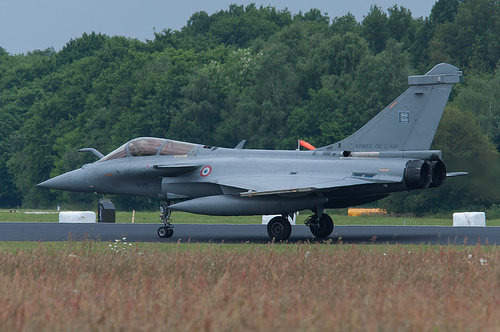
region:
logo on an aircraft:
[196, 161, 212, 181]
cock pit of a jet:
[96, 133, 197, 185]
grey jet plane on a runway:
[25, 72, 480, 249]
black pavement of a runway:
[10, 218, 104, 242]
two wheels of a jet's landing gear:
[257, 205, 349, 249]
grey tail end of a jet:
[327, 36, 468, 168]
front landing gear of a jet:
[155, 210, 176, 247]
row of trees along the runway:
[32, 30, 318, 132]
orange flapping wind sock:
[289, 128, 321, 165]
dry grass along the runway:
[39, 235, 479, 330]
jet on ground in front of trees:
[22, 51, 467, 258]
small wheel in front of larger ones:
[142, 211, 342, 241]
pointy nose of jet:
[25, 122, 160, 197]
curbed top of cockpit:
[96, 125, 201, 160]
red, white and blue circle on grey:
[191, 152, 216, 182]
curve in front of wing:
[320, 50, 455, 147]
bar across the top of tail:
[385, 56, 465, 116]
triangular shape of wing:
[205, 166, 350, 216]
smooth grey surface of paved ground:
[25, 212, 482, 247]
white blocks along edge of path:
[51, 208, 489, 229]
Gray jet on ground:
[69, 82, 426, 280]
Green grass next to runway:
[146, 235, 246, 260]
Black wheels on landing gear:
[136, 215, 383, 235]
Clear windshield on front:
[71, 133, 209, 218]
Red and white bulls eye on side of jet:
[195, 153, 232, 201]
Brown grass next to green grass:
[68, 242, 234, 326]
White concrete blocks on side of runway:
[40, 189, 165, 237]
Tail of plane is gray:
[330, 60, 467, 226]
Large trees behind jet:
[12, 37, 339, 159]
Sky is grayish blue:
[36, 15, 86, 31]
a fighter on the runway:
[29, 55, 476, 236]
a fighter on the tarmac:
[31, 55, 473, 248]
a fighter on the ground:
[30, 53, 472, 247]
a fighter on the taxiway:
[27, 59, 472, 246]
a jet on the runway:
[30, 61, 473, 248]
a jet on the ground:
[36, 57, 473, 251]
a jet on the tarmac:
[30, 55, 482, 250]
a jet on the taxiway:
[34, 60, 475, 248]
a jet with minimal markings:
[34, 56, 469, 239]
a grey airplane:
[25, 50, 486, 242]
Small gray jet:
[35, 62, 466, 233]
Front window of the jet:
[93, 128, 193, 156]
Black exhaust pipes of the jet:
[405, 155, 445, 190]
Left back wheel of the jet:
[263, 212, 290, 238]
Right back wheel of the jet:
[305, 205, 335, 240]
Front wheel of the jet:
[156, 210, 173, 238]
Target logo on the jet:
[198, 162, 209, 174]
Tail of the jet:
[317, 58, 458, 145]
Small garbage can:
[97, 196, 115, 217]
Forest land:
[1, 4, 498, 224]